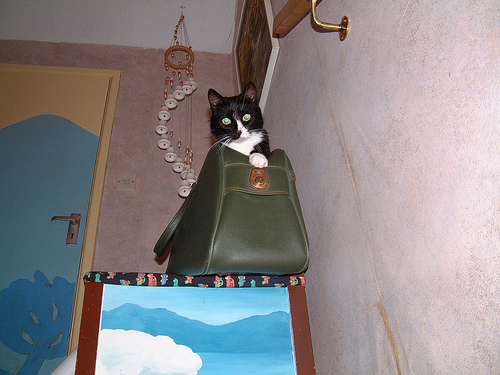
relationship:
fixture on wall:
[293, 11, 350, 45] [275, 18, 467, 254]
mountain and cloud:
[13, 88, 100, 214] [102, 306, 196, 362]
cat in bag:
[194, 65, 295, 159] [151, 142, 310, 280]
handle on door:
[53, 207, 82, 241] [90, 264, 297, 375]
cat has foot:
[194, 65, 295, 159] [244, 149, 273, 172]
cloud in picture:
[102, 306, 196, 362] [90, 264, 297, 375]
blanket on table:
[105, 260, 285, 304] [70, 263, 153, 324]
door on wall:
[90, 264, 297, 375] [275, 18, 467, 254]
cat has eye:
[194, 65, 295, 159] [216, 106, 238, 134]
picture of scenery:
[90, 264, 297, 375] [93, 287, 286, 349]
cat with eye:
[194, 65, 295, 159] [216, 106, 238, 134]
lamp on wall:
[272, 8, 341, 38] [275, 18, 467, 254]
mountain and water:
[13, 88, 100, 214] [220, 338, 261, 373]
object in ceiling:
[154, 6, 204, 80] [57, 14, 233, 60]